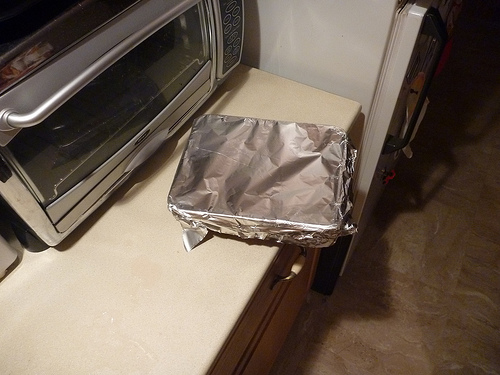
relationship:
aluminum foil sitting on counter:
[164, 111, 359, 253] [4, 65, 363, 373]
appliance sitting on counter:
[0, 0, 246, 248] [4, 65, 363, 373]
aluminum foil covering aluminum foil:
[164, 111, 360, 254] [164, 111, 359, 253]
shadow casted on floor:
[270, 240, 393, 373] [267, 2, 483, 371]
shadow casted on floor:
[379, 57, 499, 234] [267, 2, 483, 371]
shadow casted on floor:
[417, 148, 483, 371] [267, 2, 483, 371]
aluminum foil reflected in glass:
[164, 111, 360, 254] [7, 2, 212, 204]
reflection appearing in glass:
[26, 49, 166, 166] [7, 2, 212, 204]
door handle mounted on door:
[0, 1, 199, 133] [2, 2, 218, 250]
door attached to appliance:
[2, 2, 218, 250] [0, 0, 246, 248]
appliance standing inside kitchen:
[2, 3, 245, 249] [2, 2, 483, 370]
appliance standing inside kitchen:
[244, 1, 452, 299] [2, 2, 483, 370]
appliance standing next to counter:
[239, 1, 445, 296] [4, 65, 363, 373]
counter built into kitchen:
[4, 63, 361, 375] [2, 2, 483, 370]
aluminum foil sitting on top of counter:
[164, 111, 359, 253] [4, 65, 363, 373]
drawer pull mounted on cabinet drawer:
[268, 246, 309, 290] [206, 241, 299, 372]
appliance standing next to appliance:
[0, 0, 246, 248] [239, 1, 445, 296]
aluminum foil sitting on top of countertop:
[164, 111, 359, 253] [1, 62, 363, 372]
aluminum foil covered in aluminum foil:
[164, 111, 359, 253] [164, 107, 347, 235]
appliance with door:
[0, 0, 246, 248] [2, 2, 218, 250]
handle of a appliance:
[381, 10, 445, 156] [239, 1, 445, 296]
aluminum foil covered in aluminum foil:
[164, 111, 359, 253] [164, 111, 359, 253]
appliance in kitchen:
[239, 1, 445, 296] [2, 2, 483, 370]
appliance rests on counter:
[0, 0, 246, 248] [4, 65, 363, 373]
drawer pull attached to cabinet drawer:
[268, 246, 309, 290] [206, 240, 315, 374]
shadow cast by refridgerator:
[379, 57, 499, 234] [254, 8, 453, 318]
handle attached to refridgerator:
[381, 10, 445, 156] [254, 8, 453, 318]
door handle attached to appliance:
[0, 1, 199, 133] [0, 0, 246, 248]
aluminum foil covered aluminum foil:
[164, 111, 359, 253] [164, 111, 359, 253]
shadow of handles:
[379, 57, 499, 234] [389, 14, 450, 156]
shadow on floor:
[379, 57, 499, 234] [314, 49, 480, 362]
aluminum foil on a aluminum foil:
[164, 111, 359, 253] [164, 111, 359, 253]